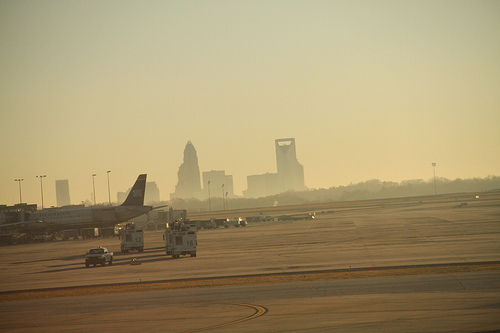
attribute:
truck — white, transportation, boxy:
[170, 224, 210, 261]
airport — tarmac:
[103, 145, 442, 330]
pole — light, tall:
[93, 158, 131, 212]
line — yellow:
[232, 301, 264, 326]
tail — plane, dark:
[103, 155, 153, 231]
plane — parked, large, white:
[1, 158, 181, 259]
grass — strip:
[251, 262, 312, 294]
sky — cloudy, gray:
[162, 26, 386, 110]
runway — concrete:
[315, 209, 490, 255]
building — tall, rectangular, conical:
[174, 129, 213, 206]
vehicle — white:
[117, 222, 147, 250]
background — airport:
[5, 42, 455, 308]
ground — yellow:
[214, 290, 271, 325]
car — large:
[117, 223, 155, 262]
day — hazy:
[105, 14, 330, 89]